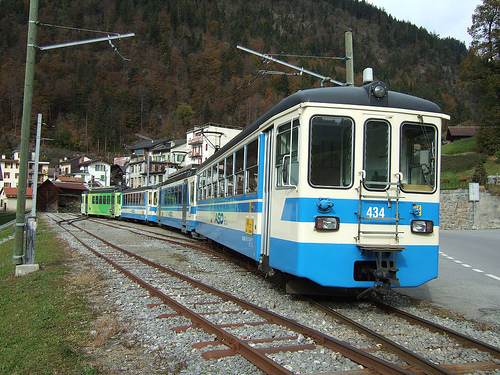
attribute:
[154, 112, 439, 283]
train — blue, stripes, white, brown, rusty, broken, green, empty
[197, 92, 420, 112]
roof — black, brown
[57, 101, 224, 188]
houses — white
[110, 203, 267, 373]
train tracks — rusty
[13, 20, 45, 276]
post — green, wooden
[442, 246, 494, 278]
lines — white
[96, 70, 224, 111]
trees — brown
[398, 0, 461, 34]
sky — white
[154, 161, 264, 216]
windows — closed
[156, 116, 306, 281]
doors — closed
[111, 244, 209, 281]
gravels — gray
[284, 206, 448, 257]
lights — off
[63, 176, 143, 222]
train — green